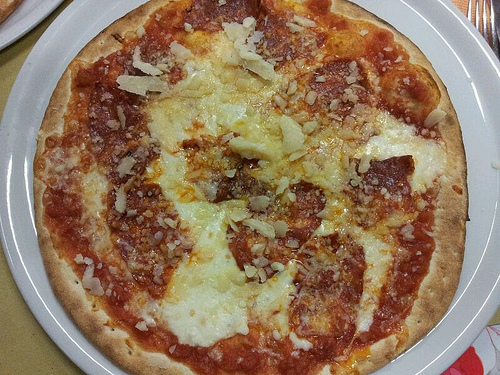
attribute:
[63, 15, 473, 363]
pizza — plain, white, edged, tasty, round, small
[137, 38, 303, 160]
cheese — melted, unmelted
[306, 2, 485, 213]
crust — brown, dark, burned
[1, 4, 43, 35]
pizza — in corner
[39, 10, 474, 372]
plate — round, edged, large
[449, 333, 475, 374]
napkin — white, floral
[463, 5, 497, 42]
fork — upper-right, silver, sectioned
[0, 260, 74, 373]
tablecloth — yellow, tan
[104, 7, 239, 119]
sauce — red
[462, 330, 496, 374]
tablecloth — floral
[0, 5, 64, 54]
plate — upper-left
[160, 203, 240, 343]
cheese — melted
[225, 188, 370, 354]
topping — round, delicious